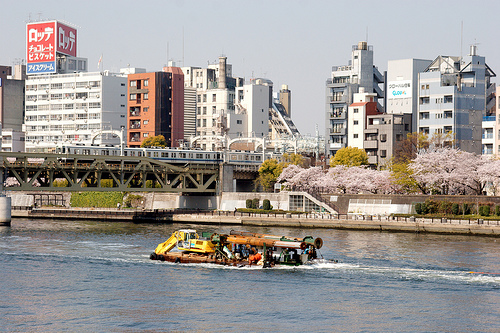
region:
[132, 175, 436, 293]
a boat in the water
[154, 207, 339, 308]
a boat in a body of water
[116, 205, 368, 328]
a boat moving in the water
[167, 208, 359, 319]
a boat moving in a body of water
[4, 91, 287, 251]
a bridge over the water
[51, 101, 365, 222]
a bridge over a body of water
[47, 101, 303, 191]
a train on a bridge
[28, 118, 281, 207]
a passenger train on a bridge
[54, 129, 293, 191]
a bridge with a train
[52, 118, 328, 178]
a bridge with passenger train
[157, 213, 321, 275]
Boat with lots of stuff on it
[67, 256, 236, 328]
clear blue waved water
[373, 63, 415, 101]
sign with blue and black lettering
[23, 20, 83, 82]
red and blue sign with lettering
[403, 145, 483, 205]
tall cherry blossom trees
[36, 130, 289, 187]
bridge with train on it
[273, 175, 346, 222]
building with glass windows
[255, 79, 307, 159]
tall building is slanted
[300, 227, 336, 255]
pipe with green end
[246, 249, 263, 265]
large orange object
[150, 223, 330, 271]
large boat in the water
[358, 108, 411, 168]
building near the water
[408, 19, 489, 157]
building near the water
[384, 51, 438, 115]
building near the water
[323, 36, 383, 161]
building near the water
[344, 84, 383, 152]
building near the water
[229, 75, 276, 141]
building near the water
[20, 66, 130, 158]
building near the water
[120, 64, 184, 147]
building near the water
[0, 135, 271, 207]
bridge over the water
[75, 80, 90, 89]
window on white building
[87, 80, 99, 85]
window on white building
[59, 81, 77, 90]
window on white building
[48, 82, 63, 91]
window on white building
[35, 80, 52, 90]
window on white building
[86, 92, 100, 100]
window on white building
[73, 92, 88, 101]
window on white building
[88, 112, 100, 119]
window on white building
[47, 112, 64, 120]
window on white building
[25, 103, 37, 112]
window on white building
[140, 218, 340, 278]
Boat taking on water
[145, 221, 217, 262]
boat carrying a tractor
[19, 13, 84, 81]
Huge red and blue sign on top of building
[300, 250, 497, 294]
waves made by the boat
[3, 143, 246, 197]
Bridge over the water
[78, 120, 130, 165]
Archs over the bridge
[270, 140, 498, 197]
White flowered trees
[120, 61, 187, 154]
only building that is a different color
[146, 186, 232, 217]
Shadow under the bridge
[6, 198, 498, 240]
Long concrete sea wall